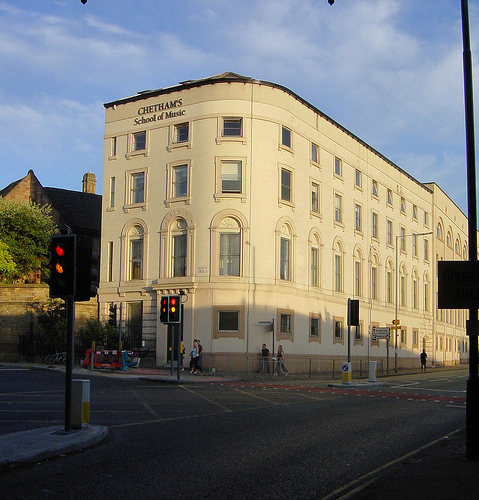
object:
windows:
[275, 159, 431, 262]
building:
[95, 72, 477, 376]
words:
[134, 98, 186, 125]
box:
[342, 363, 351, 382]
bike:
[44, 351, 67, 366]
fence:
[15, 328, 139, 361]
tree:
[1, 195, 66, 290]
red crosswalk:
[226, 377, 468, 406]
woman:
[274, 344, 289, 377]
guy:
[420, 347, 427, 373]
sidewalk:
[195, 360, 473, 381]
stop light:
[160, 295, 182, 380]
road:
[0, 375, 476, 495]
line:
[316, 421, 466, 500]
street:
[3, 364, 473, 495]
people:
[179, 338, 203, 374]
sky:
[0, 2, 474, 192]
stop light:
[45, 232, 76, 298]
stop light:
[159, 295, 181, 324]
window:
[218, 310, 239, 331]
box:
[68, 378, 90, 429]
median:
[0, 419, 111, 470]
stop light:
[42, 232, 101, 328]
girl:
[273, 345, 289, 377]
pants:
[274, 359, 288, 375]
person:
[45, 355, 55, 365]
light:
[55, 263, 63, 273]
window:
[159, 213, 195, 280]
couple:
[255, 343, 289, 377]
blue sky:
[3, 2, 475, 199]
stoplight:
[160, 295, 181, 324]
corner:
[133, 370, 234, 385]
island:
[0, 416, 112, 469]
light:
[159, 294, 181, 323]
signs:
[371, 326, 390, 343]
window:
[217, 214, 244, 277]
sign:
[371, 320, 401, 342]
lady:
[189, 339, 202, 375]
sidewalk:
[54, 356, 279, 387]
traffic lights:
[160, 294, 182, 382]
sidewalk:
[2, 351, 470, 384]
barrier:
[80, 348, 139, 368]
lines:
[102, 383, 343, 431]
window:
[215, 153, 247, 199]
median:
[210, 381, 471, 406]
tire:
[46, 354, 58, 363]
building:
[0, 168, 99, 364]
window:
[220, 116, 244, 138]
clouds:
[2, 0, 477, 220]